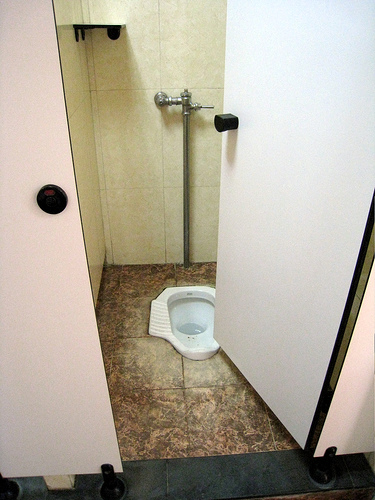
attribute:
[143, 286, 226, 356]
toilet — interesting, sink, white, clean, hole, part, here, wall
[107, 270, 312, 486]
floor — beautiful, tiled, brown, here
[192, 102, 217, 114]
handle — tall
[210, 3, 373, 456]
door — public, cracked, opened, white, here, wood, locked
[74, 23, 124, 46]
holder — strong, black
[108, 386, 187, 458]
tile — dark, green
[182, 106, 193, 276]
pipe — metallic, shiny, metal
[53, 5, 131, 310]
wall — partitioned, white, tiled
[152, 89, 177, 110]
fixture — steel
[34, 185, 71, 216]
bolt — part